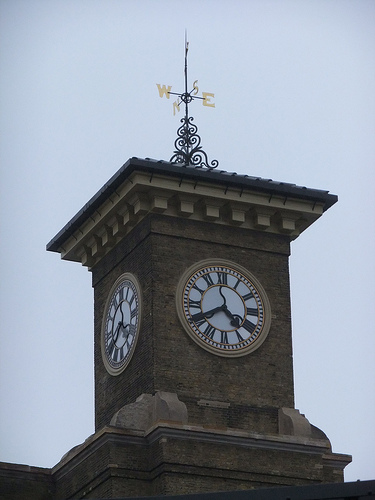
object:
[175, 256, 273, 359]
clock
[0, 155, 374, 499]
building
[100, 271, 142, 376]
clock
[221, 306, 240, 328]
hour hand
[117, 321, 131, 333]
hour hand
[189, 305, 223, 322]
minute hand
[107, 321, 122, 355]
minute hand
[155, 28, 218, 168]
weather vane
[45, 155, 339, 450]
clock tower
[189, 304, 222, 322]
hands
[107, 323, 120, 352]
hands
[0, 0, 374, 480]
sky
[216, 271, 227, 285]
number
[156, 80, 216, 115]
letters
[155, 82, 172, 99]
w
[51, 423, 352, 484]
ledge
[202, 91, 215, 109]
e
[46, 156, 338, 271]
decoration